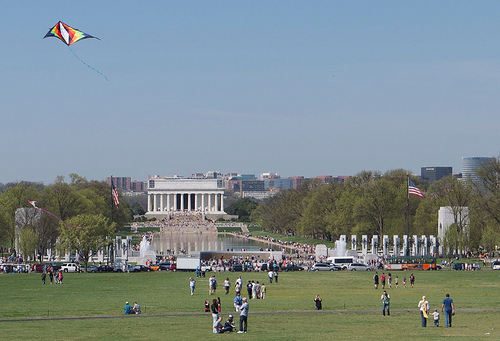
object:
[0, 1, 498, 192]
sky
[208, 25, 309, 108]
clouds